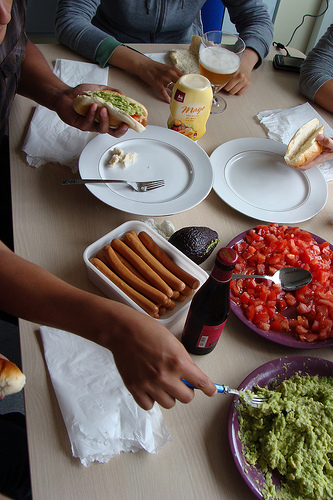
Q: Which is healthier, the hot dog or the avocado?
A: The avocado is healthier than the hot dog.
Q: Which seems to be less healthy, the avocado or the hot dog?
A: The hot dog is less healthy than the avocado.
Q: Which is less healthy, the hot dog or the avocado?
A: The hot dog is less healthy than the avocado.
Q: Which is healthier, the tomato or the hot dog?
A: The tomato is healthier than the hot dog.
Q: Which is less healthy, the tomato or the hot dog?
A: The hot dog is less healthy than the tomato.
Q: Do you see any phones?
A: Yes, there is a phone.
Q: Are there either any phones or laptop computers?
A: Yes, there is a phone.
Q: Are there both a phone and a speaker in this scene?
A: No, there is a phone but no speakers.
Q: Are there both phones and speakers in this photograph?
A: No, there is a phone but no speakers.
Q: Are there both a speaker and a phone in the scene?
A: No, there is a phone but no speakers.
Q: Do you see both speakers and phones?
A: No, there is a phone but no speakers.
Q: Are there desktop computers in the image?
A: No, there are no desktop computers.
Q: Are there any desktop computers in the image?
A: No, there are no desktop computers.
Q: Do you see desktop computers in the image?
A: No, there are no desktop computers.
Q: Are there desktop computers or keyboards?
A: No, there are no desktop computers or keyboards.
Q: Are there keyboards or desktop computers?
A: No, there are no desktop computers or keyboards.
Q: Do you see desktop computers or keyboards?
A: No, there are no desktop computers or keyboards.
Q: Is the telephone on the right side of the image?
A: Yes, the telephone is on the right of the image.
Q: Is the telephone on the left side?
A: No, the telephone is on the right of the image.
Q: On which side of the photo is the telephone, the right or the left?
A: The telephone is on the right of the image.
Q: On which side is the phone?
A: The phone is on the right of the image.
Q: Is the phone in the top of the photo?
A: Yes, the phone is in the top of the image.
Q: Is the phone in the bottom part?
A: No, the phone is in the top of the image.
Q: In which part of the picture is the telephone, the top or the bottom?
A: The telephone is in the top of the image.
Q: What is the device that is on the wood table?
A: The device is a phone.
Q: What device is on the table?
A: The device is a phone.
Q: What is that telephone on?
A: The telephone is on the table.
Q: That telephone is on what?
A: The telephone is on the table.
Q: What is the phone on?
A: The telephone is on the table.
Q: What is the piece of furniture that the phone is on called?
A: The piece of furniture is a table.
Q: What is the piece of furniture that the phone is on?
A: The piece of furniture is a table.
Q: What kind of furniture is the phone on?
A: The phone is on the table.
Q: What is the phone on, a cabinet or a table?
A: The phone is on a table.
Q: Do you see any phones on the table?
A: Yes, there is a phone on the table.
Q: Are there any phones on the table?
A: Yes, there is a phone on the table.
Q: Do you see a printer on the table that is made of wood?
A: No, there is a phone on the table.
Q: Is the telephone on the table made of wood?
A: Yes, the telephone is on the table.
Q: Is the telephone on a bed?
A: No, the telephone is on the table.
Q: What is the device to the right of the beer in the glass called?
A: The device is a phone.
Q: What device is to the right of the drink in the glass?
A: The device is a phone.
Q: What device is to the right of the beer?
A: The device is a phone.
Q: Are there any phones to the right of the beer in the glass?
A: Yes, there is a phone to the right of the beer.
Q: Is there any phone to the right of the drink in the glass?
A: Yes, there is a phone to the right of the beer.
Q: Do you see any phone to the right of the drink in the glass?
A: Yes, there is a phone to the right of the beer.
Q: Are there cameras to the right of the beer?
A: No, there is a phone to the right of the beer.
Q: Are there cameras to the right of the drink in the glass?
A: No, there is a phone to the right of the beer.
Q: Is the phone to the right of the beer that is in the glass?
A: Yes, the phone is to the right of the beer.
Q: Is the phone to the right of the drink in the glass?
A: Yes, the phone is to the right of the beer.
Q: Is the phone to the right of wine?
A: No, the phone is to the right of the beer.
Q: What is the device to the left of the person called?
A: The device is a phone.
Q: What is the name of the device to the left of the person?
A: The device is a phone.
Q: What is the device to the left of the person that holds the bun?
A: The device is a phone.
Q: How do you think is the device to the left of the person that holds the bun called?
A: The device is a phone.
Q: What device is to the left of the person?
A: The device is a phone.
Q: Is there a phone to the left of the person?
A: Yes, there is a phone to the left of the person.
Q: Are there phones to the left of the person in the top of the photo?
A: Yes, there is a phone to the left of the person.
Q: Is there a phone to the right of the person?
A: No, the phone is to the left of the person.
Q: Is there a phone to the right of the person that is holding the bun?
A: No, the phone is to the left of the person.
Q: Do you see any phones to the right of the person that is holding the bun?
A: No, the phone is to the left of the person.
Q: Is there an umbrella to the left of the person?
A: No, there is a phone to the left of the person.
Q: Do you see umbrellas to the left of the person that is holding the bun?
A: No, there is a phone to the left of the person.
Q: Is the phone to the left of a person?
A: Yes, the phone is to the left of a person.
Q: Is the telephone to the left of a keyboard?
A: No, the telephone is to the left of a person.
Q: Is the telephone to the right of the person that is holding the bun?
A: No, the telephone is to the left of the person.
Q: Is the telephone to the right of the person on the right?
A: No, the telephone is to the left of the person.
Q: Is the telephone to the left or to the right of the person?
A: The telephone is to the left of the person.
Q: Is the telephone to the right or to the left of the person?
A: The telephone is to the left of the person.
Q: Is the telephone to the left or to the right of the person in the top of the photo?
A: The telephone is to the left of the person.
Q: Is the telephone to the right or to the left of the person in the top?
A: The telephone is to the left of the person.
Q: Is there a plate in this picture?
A: Yes, there is a plate.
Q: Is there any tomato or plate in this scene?
A: Yes, there is a plate.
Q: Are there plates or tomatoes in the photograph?
A: Yes, there is a plate.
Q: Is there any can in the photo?
A: No, there are no cans.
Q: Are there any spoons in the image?
A: Yes, there is a spoon.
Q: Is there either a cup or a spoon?
A: Yes, there is a spoon.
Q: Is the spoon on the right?
A: Yes, the spoon is on the right of the image.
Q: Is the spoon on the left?
A: No, the spoon is on the right of the image.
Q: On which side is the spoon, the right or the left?
A: The spoon is on the right of the image.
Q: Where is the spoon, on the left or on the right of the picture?
A: The spoon is on the right of the image.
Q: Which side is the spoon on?
A: The spoon is on the right of the image.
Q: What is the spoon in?
A: The spoon is in the plate.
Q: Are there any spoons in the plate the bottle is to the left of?
A: Yes, there is a spoon in the plate.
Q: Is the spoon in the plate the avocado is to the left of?
A: Yes, the spoon is in the plate.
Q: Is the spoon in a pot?
A: No, the spoon is in the plate.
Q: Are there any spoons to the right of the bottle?
A: Yes, there is a spoon to the right of the bottle.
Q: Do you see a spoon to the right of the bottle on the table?
A: Yes, there is a spoon to the right of the bottle.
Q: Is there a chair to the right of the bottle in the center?
A: No, there is a spoon to the right of the bottle.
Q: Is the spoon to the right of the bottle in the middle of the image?
A: Yes, the spoon is to the right of the bottle.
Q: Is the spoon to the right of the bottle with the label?
A: Yes, the spoon is to the right of the bottle.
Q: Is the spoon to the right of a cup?
A: No, the spoon is to the right of the bottle.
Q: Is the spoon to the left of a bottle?
A: No, the spoon is to the right of a bottle.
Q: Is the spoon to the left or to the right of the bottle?
A: The spoon is to the right of the bottle.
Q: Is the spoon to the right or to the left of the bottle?
A: The spoon is to the right of the bottle.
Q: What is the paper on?
A: The paper is on the table.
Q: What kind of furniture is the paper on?
A: The paper is on the table.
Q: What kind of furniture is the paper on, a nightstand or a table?
A: The paper is on a table.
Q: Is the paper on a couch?
A: No, the paper is on the table.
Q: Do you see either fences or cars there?
A: No, there are no fences or cars.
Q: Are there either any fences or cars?
A: No, there are no fences or cars.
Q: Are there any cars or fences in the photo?
A: No, there are no fences or cars.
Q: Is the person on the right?
A: Yes, the person is on the right of the image.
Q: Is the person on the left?
A: No, the person is on the right of the image.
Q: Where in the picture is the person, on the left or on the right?
A: The person is on the right of the image.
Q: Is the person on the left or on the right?
A: The person is on the right of the image.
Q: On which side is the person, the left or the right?
A: The person is on the right of the image.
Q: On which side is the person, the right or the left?
A: The person is on the right of the image.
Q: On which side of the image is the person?
A: The person is on the right of the image.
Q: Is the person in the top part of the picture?
A: Yes, the person is in the top of the image.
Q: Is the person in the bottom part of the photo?
A: No, the person is in the top of the image.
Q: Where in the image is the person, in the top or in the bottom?
A: The person is in the top of the image.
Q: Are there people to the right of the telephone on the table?
A: Yes, there is a person to the right of the phone.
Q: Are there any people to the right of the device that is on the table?
A: Yes, there is a person to the right of the phone.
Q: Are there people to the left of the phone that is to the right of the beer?
A: No, the person is to the right of the phone.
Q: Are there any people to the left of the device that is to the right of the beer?
A: No, the person is to the right of the phone.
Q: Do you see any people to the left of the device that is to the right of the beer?
A: No, the person is to the right of the phone.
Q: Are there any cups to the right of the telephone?
A: No, there is a person to the right of the telephone.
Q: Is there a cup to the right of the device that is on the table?
A: No, there is a person to the right of the telephone.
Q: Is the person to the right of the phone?
A: Yes, the person is to the right of the phone.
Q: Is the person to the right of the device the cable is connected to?
A: Yes, the person is to the right of the phone.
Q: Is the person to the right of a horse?
A: No, the person is to the right of the phone.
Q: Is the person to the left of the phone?
A: No, the person is to the right of the phone.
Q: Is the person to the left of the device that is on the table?
A: No, the person is to the right of the phone.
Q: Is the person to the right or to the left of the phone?
A: The person is to the right of the phone.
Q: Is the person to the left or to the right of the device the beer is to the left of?
A: The person is to the right of the phone.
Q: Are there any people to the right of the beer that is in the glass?
A: Yes, there is a person to the right of the beer.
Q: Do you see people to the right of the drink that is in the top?
A: Yes, there is a person to the right of the beer.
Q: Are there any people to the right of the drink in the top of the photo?
A: Yes, there is a person to the right of the beer.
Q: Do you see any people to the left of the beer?
A: No, the person is to the right of the beer.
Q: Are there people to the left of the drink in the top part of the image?
A: No, the person is to the right of the beer.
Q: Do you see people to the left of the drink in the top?
A: No, the person is to the right of the beer.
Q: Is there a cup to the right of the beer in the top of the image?
A: No, there is a person to the right of the beer.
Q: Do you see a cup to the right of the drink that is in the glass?
A: No, there is a person to the right of the beer.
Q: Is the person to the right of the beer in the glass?
A: Yes, the person is to the right of the beer.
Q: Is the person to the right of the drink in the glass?
A: Yes, the person is to the right of the beer.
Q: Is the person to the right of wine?
A: No, the person is to the right of the beer.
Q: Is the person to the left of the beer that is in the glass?
A: No, the person is to the right of the beer.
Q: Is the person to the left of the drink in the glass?
A: No, the person is to the right of the beer.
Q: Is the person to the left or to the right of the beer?
A: The person is to the right of the beer.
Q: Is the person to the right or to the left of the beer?
A: The person is to the right of the beer.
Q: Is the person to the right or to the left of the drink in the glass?
A: The person is to the right of the beer.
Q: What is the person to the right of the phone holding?
A: The person is holding the bun.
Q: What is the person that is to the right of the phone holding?
A: The person is holding the bun.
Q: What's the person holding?
A: The person is holding the bun.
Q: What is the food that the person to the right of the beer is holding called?
A: The food is a bun.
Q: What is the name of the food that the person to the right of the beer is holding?
A: The food is a bun.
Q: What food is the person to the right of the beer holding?
A: The person is holding the bun.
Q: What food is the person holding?
A: The person is holding the bun.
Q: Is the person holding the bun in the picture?
A: Yes, the person is holding the bun.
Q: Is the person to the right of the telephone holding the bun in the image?
A: Yes, the person is holding the bun.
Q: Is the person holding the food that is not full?
A: Yes, the person is holding the bun.